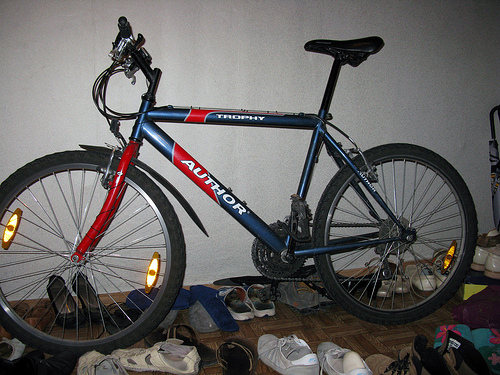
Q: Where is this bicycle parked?
A: In the house.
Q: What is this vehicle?
A: Bicycle.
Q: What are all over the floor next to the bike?
A: Shoes.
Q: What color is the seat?
A: Black.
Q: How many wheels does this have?
A: Two.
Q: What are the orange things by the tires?
A: Reflectors.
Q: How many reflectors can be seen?
A: Three.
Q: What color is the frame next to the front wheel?
A: Red.